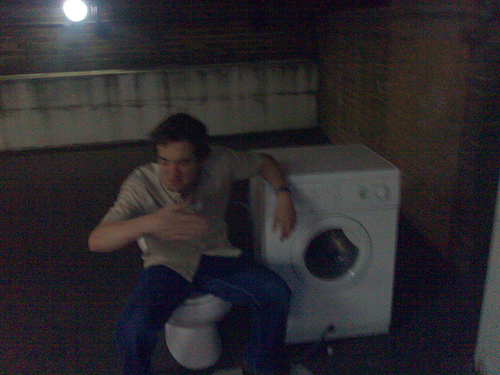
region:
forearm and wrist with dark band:
[260, 156, 310, 251]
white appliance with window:
[246, 131, 402, 346]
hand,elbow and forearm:
[83, 194, 222, 268]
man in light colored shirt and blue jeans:
[101, 111, 293, 369]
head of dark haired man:
[137, 106, 218, 198]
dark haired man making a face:
[138, 108, 221, 200]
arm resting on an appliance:
[250, 138, 407, 272]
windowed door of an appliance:
[293, 211, 388, 306]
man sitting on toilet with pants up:
[98, 106, 293, 367]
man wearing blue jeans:
[100, 106, 287, 373]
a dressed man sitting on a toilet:
[85, 112, 297, 374]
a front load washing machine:
[256, 141, 397, 338]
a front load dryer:
[252, 145, 397, 336]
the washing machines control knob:
[373, 180, 388, 202]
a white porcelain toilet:
[166, 293, 228, 371]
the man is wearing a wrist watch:
[271, 182, 291, 194]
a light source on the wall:
[62, 0, 89, 24]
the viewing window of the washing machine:
[293, 213, 369, 289]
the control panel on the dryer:
[292, 176, 399, 210]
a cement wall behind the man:
[1, 64, 322, 116]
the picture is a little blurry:
[1, 35, 467, 364]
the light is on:
[30, 0, 128, 65]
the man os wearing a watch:
[235, 175, 315, 206]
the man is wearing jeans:
[104, 259, 311, 361]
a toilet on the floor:
[152, 271, 234, 368]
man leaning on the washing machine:
[228, 123, 418, 355]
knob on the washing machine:
[367, 177, 392, 211]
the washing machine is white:
[235, 120, 417, 352]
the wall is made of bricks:
[315, 6, 474, 193]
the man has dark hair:
[138, 102, 220, 174]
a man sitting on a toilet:
[76, 98, 319, 373]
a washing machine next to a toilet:
[228, 130, 440, 345]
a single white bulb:
[56, 2, 99, 41]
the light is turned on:
[60, 2, 95, 28]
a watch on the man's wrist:
[272, 176, 289, 202]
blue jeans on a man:
[108, 253, 346, 374]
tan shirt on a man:
[96, 148, 278, 286]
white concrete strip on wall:
[0, 59, 317, 154]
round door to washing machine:
[292, 211, 389, 300]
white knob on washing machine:
[371, 178, 397, 210]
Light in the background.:
[53, 0, 108, 32]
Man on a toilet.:
[114, 112, 296, 358]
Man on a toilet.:
[163, 288, 229, 369]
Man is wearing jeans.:
[133, 241, 298, 373]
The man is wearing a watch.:
[267, 182, 297, 206]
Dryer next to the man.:
[237, 146, 417, 349]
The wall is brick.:
[346, 15, 483, 161]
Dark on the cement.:
[30, 78, 154, 108]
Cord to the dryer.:
[278, 322, 350, 373]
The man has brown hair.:
[138, 106, 217, 171]